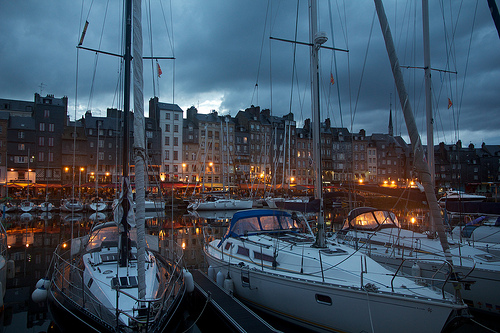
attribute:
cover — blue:
[224, 206, 306, 237]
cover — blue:
[341, 203, 402, 231]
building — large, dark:
[6, 90, 274, 200]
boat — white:
[200, 210, 463, 331]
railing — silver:
[34, 236, 213, 329]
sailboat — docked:
[65, 175, 187, 311]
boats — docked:
[53, 168, 475, 303]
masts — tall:
[64, 4, 481, 324]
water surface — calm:
[8, 221, 61, 283]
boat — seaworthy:
[183, 192, 254, 214]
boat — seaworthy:
[438, 181, 485, 211]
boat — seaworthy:
[41, 218, 197, 329]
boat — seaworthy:
[200, 202, 472, 329]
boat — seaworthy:
[323, 204, 499, 321]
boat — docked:
[211, 222, 411, 322]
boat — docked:
[347, 208, 487, 294]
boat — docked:
[431, 210, 499, 240]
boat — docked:
[59, 230, 214, 331]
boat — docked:
[187, 190, 257, 213]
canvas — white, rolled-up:
[130, 4, 167, 302]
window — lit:
[349, 210, 378, 232]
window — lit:
[373, 210, 394, 228]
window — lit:
[389, 210, 403, 228]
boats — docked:
[54, 34, 175, 317]